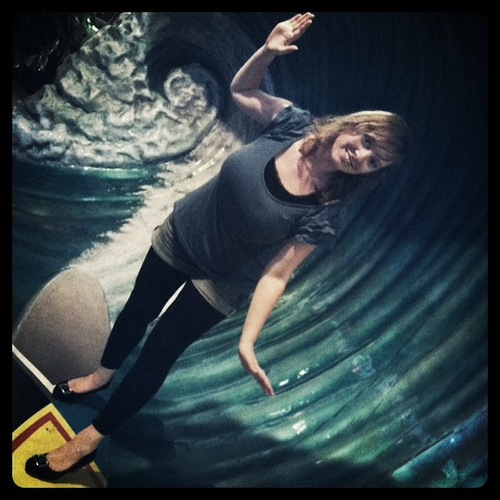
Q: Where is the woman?
A: Tunnel.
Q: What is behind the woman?
A: Rush of water.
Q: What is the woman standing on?
A: Surfboard.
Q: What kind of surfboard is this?
A: Yellow and grey.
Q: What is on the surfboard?
A: Yellow diamond.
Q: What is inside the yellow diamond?
A: Red line.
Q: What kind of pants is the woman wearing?
A: Black pants.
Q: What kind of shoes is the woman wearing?
A: Black shoes.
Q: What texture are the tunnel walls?
A: Ridged.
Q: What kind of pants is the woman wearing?
A: Black leggings.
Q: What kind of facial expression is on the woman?
A: Smile.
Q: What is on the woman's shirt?
A: Grey and black.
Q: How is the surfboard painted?
A: Multi colors.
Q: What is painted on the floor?
A: Optical illusion.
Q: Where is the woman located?
A: Inside a tube.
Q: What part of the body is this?
A: Arm.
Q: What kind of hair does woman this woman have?
A: Blonde.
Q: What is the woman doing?
A: Smiling.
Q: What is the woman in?
A: A tunnel.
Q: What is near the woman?
A: A tunnel.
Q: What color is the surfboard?
A: Gray, black, yellow, and red.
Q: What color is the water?
A: Blue and white.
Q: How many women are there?
A: One.